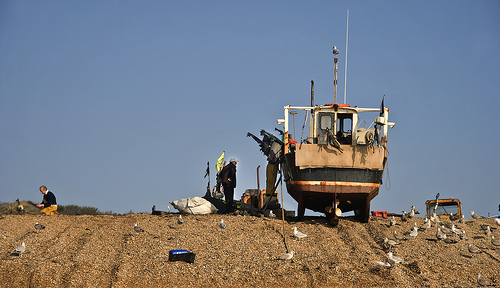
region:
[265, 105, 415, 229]
OLD BOAT ON SAND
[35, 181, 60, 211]
MAN KNEELING ON SAND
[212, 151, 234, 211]
MAN STANDING BY OLD BOAT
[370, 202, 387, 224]
SMALL RED BOX ON SAND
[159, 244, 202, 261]
BLUE AND BLACK OBJECT ON SAND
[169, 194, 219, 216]
LARGE WHITE BAG ON SAND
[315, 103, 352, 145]
SMALL CABIN ON OLD BOAT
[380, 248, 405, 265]
WHITE AND GRAY SEAGULL ON SAND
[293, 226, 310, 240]
WHITE AND GRAY SEAGULL ON SAND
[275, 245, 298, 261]
WHITE AND GRAY SEAGULL ON SAND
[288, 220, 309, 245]
bird on the ground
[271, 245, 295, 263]
bird that is not in flight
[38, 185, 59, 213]
man sitting on ground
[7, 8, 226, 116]
the clear blue sky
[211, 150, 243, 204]
man standing on grass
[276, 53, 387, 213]
old vehicle on land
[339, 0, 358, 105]
white pole coming from top of vehicle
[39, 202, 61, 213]
the man's yellow pants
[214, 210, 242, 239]
bird on a dry field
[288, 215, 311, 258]
bird on a dry field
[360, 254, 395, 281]
bird on a dry field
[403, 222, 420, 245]
bird on a dry field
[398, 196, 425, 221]
bird on a dry field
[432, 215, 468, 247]
bird on a dry field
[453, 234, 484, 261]
bird on a dry field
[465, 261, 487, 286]
bird on a dry field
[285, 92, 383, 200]
brown machine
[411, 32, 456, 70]
white clouds in blue sky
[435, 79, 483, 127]
white clouds in blue sky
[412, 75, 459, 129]
white clouds in blue sky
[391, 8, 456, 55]
white clouds in blue sky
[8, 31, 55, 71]
white clouds in blue sky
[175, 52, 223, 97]
white clouds in blue sky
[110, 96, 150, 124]
white clouds in blue sky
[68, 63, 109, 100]
white clouds in blue sky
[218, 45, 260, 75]
white clouds in blue sky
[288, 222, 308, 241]
bird in the sand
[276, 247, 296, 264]
bird in the sand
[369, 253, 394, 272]
bird in the sand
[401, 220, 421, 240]
white bird in the sand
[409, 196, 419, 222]
white bird in the sand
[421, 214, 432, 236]
white bird in the sand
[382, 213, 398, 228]
white bird in the sand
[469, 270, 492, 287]
white bird in the sand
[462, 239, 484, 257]
white bird in the sand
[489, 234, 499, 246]
white bird in the sand